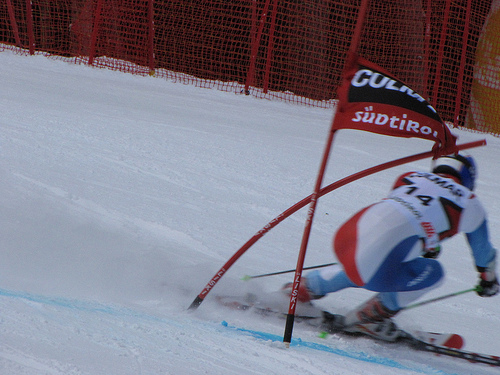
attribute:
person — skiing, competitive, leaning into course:
[264, 150, 499, 346]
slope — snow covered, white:
[4, 45, 499, 373]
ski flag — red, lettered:
[259, 3, 460, 343]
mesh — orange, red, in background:
[2, 2, 499, 137]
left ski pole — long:
[244, 245, 341, 298]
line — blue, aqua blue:
[2, 283, 411, 372]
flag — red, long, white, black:
[334, 54, 457, 155]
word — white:
[353, 101, 443, 140]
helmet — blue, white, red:
[433, 150, 477, 190]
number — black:
[408, 182, 435, 210]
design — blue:
[368, 235, 442, 294]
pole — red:
[188, 135, 490, 315]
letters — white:
[199, 267, 226, 302]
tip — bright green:
[242, 274, 253, 284]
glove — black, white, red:
[477, 265, 499, 299]